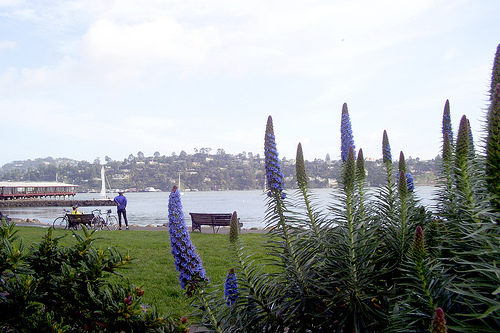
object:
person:
[71, 205, 85, 227]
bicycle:
[91, 208, 119, 232]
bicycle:
[53, 208, 81, 230]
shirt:
[113, 194, 127, 209]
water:
[0, 188, 457, 228]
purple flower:
[339, 102, 356, 162]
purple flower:
[263, 114, 287, 199]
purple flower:
[167, 184, 210, 290]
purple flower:
[441, 99, 453, 158]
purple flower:
[223, 268, 240, 308]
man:
[113, 192, 130, 231]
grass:
[1, 222, 312, 332]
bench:
[189, 210, 244, 234]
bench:
[71, 205, 84, 220]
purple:
[116, 199, 127, 205]